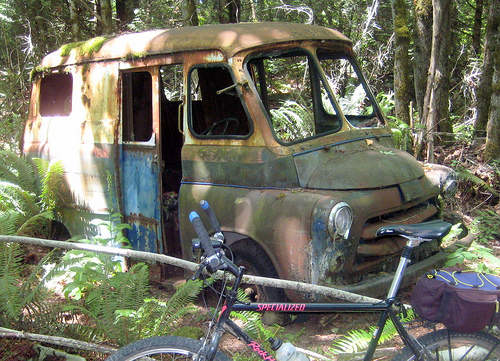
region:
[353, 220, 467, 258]
black padded seat on bicycle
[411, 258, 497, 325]
maroon bag on back of bike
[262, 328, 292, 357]
water bottle with black lid on bike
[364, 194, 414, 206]
brown rusted area on car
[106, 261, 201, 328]
fern type plant on ground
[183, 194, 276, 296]
black handlebars on bike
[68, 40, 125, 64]
green moss on car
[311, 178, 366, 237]
right front headlight on car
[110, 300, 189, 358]
black front tire on bike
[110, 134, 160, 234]
blue rusted door on car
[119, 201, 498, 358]
Bicycle with pink writing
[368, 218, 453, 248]
Bicycle seat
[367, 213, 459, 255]
Black bicycle seat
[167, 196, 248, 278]
Bicycle handles with blue ends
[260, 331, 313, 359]
Part of a water bottle with a black top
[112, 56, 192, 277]
Door with rust on an old car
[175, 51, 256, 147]
Car window with rust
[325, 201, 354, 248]
Car headlight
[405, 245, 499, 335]
Package in a purple and blue bag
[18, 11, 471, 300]
rusted old van in the woods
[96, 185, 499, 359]
black mountain bike in the woods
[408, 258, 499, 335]
dark purple and blue cargo bag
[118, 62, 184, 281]
van has a sliding door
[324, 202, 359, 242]
broken front headlight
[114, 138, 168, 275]
some blue paint remains on the door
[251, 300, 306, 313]
the word "specialized" in red lettering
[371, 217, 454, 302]
seat of the bike is raised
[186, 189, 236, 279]
front handlebars of the bike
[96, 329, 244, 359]
front tire of the bike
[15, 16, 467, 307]
This is a rusted vehicle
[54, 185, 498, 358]
This is a black bike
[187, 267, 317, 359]
The paint is pink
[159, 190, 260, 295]
Black and blue handles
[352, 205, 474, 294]
This is a black seat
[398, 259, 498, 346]
A purple and blue backpack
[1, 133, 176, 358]
The plant is green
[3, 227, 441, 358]
The gate is wooden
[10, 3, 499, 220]
This is a bunch of wooden trees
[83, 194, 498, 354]
Boy's pink and grey bicycle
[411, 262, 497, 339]
Dark blue and light blue carrying case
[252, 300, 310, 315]
Pink words saying SPECIALIZED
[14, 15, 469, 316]
Light brown antique bus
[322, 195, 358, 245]
Dirty old headlight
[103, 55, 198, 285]
Rusted, sliding, antique, van door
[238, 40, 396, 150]
Antique, split, front windshield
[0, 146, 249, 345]
Green forest shrubbery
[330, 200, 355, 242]
A right front headlight.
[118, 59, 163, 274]
A door on a truck.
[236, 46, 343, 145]
A passenger side window.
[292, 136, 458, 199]
A hood on a rusted truck.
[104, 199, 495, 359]
A bike in front of a truck.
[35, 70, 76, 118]
A rear passenger window.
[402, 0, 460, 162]
A brown tree in a forest.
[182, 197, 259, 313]
Handle bars on a bike.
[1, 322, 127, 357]
A branch on a wooden fence.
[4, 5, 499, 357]
a scene during the day time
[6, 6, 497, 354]
a scene in a forest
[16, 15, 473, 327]
a rundown van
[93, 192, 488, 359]
a black bike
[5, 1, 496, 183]
some trees in the background